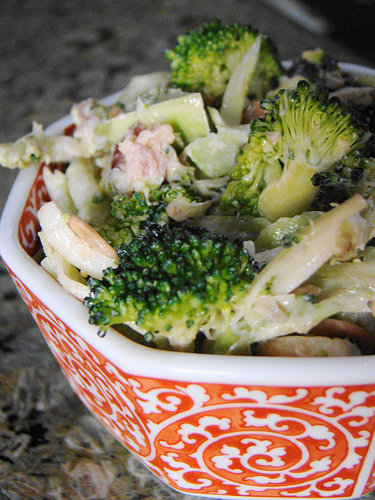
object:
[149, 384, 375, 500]
design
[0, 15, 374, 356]
asian dish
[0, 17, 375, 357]
salad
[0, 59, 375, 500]
bowl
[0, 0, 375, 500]
countertop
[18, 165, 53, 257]
design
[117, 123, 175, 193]
chicken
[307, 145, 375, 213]
broccoli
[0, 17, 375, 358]
pasta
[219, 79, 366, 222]
broccoli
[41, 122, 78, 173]
design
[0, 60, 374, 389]
rim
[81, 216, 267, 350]
piece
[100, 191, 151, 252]
broccoli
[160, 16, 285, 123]
broccoli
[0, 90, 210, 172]
broccoli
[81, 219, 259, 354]
broccoli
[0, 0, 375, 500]
table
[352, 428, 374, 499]
design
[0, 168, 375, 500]
pattern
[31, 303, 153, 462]
design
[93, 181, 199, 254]
broccoli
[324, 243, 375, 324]
sauce